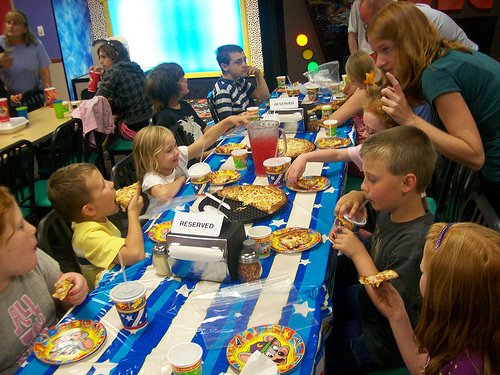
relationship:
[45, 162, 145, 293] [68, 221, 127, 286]
boy with shirt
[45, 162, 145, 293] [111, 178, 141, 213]
boy eating pizza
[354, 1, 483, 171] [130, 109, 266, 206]
adult talking to child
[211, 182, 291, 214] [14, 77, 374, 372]
pizza on table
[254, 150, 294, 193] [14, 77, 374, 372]
cup on table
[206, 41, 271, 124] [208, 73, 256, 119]
boy with shirt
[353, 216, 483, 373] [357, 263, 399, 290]
child eating pizza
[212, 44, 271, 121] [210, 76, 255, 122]
boy wearing shirt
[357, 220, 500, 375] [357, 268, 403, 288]
child eating pizza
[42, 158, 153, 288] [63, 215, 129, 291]
boy wearing shirt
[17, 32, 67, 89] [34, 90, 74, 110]
straw in drink